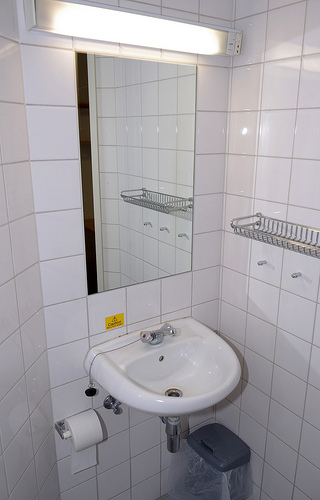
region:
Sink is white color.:
[58, 315, 252, 417]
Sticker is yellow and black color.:
[96, 310, 143, 342]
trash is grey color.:
[178, 413, 241, 497]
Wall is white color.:
[5, 313, 73, 397]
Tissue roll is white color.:
[64, 404, 117, 473]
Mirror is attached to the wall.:
[58, 168, 212, 303]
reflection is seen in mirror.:
[107, 168, 208, 244]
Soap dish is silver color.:
[222, 210, 319, 272]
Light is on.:
[23, 3, 253, 62]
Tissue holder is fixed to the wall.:
[50, 401, 123, 471]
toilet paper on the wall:
[61, 402, 114, 471]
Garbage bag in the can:
[179, 449, 249, 491]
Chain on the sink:
[82, 345, 131, 382]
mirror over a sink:
[77, 204, 219, 288]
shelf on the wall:
[232, 208, 312, 257]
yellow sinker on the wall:
[98, 311, 149, 334]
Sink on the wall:
[87, 335, 231, 422]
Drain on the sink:
[157, 422, 187, 453]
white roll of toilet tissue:
[64, 411, 100, 469]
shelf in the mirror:
[103, 151, 204, 258]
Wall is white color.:
[21, 283, 91, 386]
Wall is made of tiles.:
[8, 314, 77, 431]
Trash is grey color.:
[181, 423, 264, 499]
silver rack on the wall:
[229, 210, 319, 258]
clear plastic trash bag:
[166, 443, 252, 499]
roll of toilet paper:
[64, 409, 103, 474]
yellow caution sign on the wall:
[104, 311, 124, 329]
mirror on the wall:
[75, 51, 196, 296]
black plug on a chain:
[86, 338, 139, 397]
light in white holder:
[23, 1, 241, 55]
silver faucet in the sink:
[140, 322, 177, 343]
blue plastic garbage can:
[187, 422, 250, 498]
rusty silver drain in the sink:
[164, 387, 181, 397]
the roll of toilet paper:
[64, 407, 102, 474]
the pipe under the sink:
[155, 415, 181, 452]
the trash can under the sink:
[167, 422, 252, 499]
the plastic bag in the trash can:
[165, 440, 252, 498]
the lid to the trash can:
[185, 421, 250, 469]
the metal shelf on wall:
[229, 212, 318, 259]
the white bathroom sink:
[83, 316, 241, 417]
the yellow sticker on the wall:
[104, 312, 124, 331]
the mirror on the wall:
[74, 50, 197, 295]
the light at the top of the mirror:
[21, 0, 242, 55]